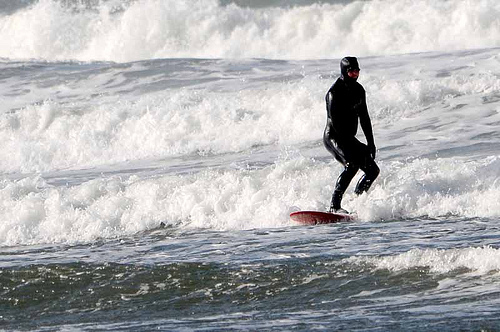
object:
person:
[324, 55, 381, 214]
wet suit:
[322, 57, 379, 207]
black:
[336, 93, 350, 110]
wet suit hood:
[340, 57, 361, 81]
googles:
[345, 66, 360, 73]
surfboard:
[290, 210, 360, 227]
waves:
[2, 156, 499, 244]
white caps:
[0, 68, 500, 174]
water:
[0, 0, 500, 332]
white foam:
[0, 154, 500, 247]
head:
[339, 56, 360, 80]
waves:
[0, 0, 497, 60]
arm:
[357, 87, 373, 145]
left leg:
[354, 139, 380, 192]